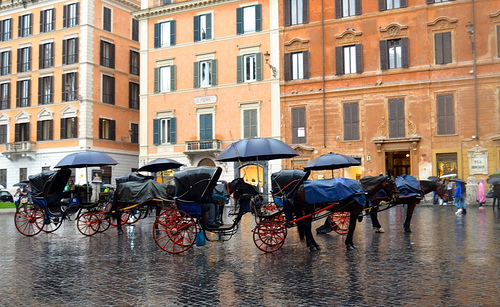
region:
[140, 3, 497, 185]
A building full of windows.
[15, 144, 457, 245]
A group of horse-drawn carriages.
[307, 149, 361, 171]
A black umbrella.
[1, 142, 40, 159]
A balcony on a building.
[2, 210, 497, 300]
A rainy wet road.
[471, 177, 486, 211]
Person in a pink raincoat.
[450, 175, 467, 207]
A person wearing blue.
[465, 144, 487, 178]
A white sign on a building.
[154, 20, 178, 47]
A window on a building.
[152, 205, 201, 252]
Red wheels of a cart.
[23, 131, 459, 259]
horse pulling carriages on street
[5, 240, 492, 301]
street made from brick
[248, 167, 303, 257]
carriage at end of horse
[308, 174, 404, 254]
horse pulling carriage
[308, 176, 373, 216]
covering on the horse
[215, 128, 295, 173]
umbrella on a carriage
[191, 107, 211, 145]
door to a building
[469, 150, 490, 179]
plaque on a wall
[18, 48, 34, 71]
window on a building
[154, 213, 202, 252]
wheel on the carriage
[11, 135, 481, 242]
a line of horses & carriages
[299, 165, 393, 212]
the horse has a blue rain jacket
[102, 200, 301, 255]
the cart wheels are red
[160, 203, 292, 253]
the wheels have spokes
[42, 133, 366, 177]
big black umbrellas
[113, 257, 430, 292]
the street is extremely wet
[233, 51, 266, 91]
shutters on the windows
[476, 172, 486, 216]
this lady is in a pink coat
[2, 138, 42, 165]
a balcony at this building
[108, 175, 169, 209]
this horse has a black raincoat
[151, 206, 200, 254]
Red rear wheel of a horse drawn carriage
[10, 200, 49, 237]
Red rear wheel of a horse drawn carriage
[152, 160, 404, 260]
black and red horse drawn carriage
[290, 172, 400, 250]
Horse for pulling a horse drawn carriage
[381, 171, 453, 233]
Horse for pulling a horse drawn carriage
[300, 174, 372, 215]
Blue jacket on a horse drawing a carriage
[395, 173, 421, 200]
Blue jacket on a horse drawing a carriage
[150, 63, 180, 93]
Window with open shutters in the background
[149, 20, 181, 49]
Window with open shutters in the background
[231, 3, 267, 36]
Window with open shutters in the background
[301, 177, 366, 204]
a waterproof blanket to keep the horse dry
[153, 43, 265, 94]
three windows in a row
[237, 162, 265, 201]
a yellow arched doorway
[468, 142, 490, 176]
a sign with writing on it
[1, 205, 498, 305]
wet cobblestone street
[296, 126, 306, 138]
a red and white sign in the window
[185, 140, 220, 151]
a balcony in front of the door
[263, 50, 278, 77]
a lamp attached to the building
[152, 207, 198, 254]
a red metal carriage wheel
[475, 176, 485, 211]
a person dressed in pink